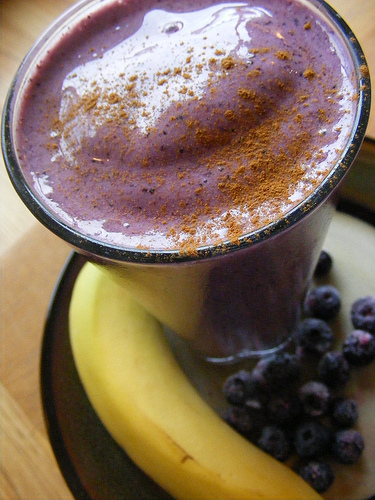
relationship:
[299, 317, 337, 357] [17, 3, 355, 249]
blueberry by smoothy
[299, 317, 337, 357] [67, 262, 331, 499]
blueberry by banana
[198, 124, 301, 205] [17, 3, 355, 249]
powder on smoothy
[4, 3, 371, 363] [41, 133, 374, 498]
glass close to plate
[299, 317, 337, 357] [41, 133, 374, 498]
blueberry with plate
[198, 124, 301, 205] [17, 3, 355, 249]
powder with smoothy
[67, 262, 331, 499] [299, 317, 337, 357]
banana with blueberry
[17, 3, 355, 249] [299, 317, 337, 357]
smoothy with blueberry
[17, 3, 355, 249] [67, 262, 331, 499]
smoothy with banana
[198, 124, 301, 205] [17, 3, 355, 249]
powder of smoothy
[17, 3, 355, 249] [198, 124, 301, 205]
smoothy with powder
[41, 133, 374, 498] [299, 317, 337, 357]
plate with blueberry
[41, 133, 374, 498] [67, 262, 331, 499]
plate with banana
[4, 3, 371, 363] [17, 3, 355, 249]
glass with smoothy